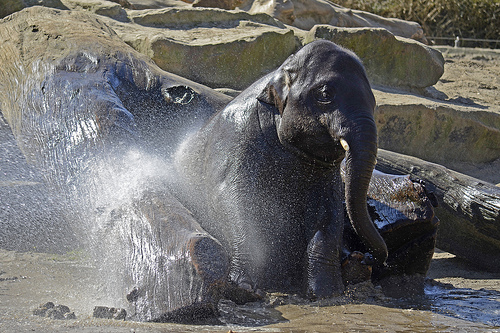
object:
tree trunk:
[0, 3, 499, 333]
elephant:
[158, 40, 393, 304]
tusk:
[336, 135, 353, 156]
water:
[0, 107, 499, 328]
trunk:
[328, 114, 395, 266]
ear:
[253, 62, 297, 118]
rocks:
[57, 0, 307, 94]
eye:
[312, 82, 336, 109]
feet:
[220, 237, 320, 305]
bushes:
[334, 0, 499, 42]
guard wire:
[427, 34, 497, 48]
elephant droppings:
[25, 298, 79, 324]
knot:
[159, 81, 202, 112]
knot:
[183, 234, 233, 288]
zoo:
[0, 0, 498, 331]